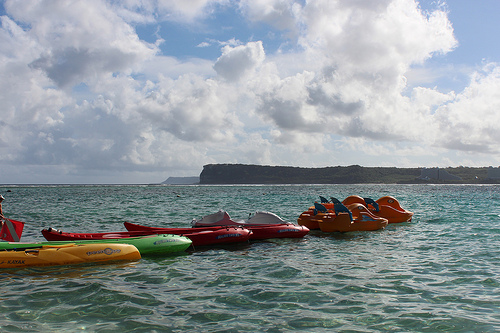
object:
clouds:
[14, 0, 162, 21]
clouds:
[459, 63, 497, 96]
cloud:
[213, 36, 266, 83]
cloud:
[41, 94, 166, 141]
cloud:
[161, 0, 215, 26]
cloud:
[229, 133, 271, 164]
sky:
[0, 0, 497, 184]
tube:
[0, 242, 142, 267]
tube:
[203, 209, 310, 239]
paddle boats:
[364, 195, 415, 224]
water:
[5, 182, 498, 329]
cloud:
[434, 63, 497, 151]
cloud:
[3, 0, 159, 74]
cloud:
[1, 57, 70, 147]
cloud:
[131, 74, 238, 145]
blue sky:
[2, 0, 498, 184]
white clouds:
[435, 86, 497, 151]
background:
[2, 73, 499, 331]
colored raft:
[95, 233, 193, 255]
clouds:
[270, 65, 331, 124]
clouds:
[299, 8, 442, 94]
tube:
[1, 233, 189, 257]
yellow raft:
[0, 238, 141, 268]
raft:
[317, 201, 386, 233]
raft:
[209, 210, 311, 239]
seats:
[327, 205, 354, 215]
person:
[0, 195, 20, 245]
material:
[0, 217, 25, 241]